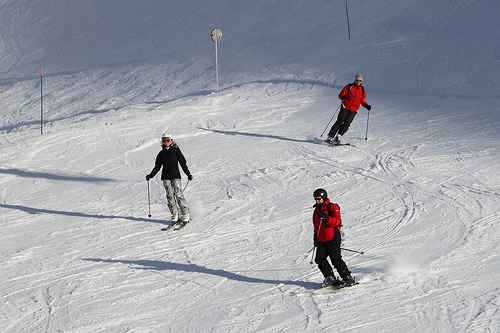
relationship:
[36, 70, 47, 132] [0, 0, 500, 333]
pole in snow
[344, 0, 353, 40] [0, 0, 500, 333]
pole in snow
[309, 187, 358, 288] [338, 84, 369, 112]
man in jacket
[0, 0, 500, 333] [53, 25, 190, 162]
snow on hill side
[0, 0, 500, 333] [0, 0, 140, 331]
snow on hill side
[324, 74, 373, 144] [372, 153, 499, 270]
man skiing on snow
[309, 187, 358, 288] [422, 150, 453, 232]
man in snow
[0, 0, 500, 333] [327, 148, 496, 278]
snow on hill side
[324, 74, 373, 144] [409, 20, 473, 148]
man on snow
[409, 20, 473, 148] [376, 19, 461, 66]
snow on hill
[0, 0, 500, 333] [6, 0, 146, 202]
snow on hillside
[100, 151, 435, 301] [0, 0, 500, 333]
tracks in snow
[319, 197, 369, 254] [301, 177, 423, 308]
jacket on a man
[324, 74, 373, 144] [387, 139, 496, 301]
man on a slope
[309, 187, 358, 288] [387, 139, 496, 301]
man on a slope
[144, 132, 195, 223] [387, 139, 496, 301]
person on a slope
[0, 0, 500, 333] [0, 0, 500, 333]
snow on a ground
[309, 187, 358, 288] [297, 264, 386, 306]
man on snow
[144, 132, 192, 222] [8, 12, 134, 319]
person on snow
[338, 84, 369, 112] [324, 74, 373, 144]
jacket on man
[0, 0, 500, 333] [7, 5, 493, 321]
snow on ground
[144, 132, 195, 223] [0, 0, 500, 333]
person on snow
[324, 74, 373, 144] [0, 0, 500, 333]
man on snow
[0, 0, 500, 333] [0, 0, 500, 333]
snow on ground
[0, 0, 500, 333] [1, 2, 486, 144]
snow on hill